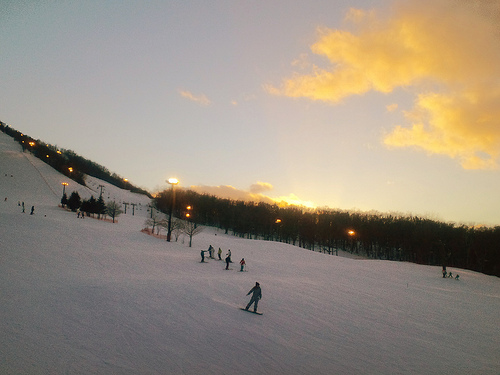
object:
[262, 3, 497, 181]
cloud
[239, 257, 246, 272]
skier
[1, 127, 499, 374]
slope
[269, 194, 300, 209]
sun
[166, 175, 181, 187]
light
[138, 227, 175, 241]
fence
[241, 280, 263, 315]
boarder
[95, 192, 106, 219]
tree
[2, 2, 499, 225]
sky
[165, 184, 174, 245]
pole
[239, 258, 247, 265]
jacket